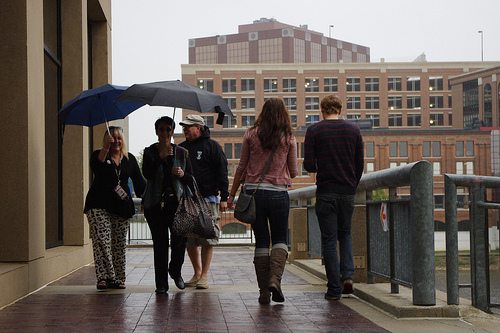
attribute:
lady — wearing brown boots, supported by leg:
[230, 97, 297, 307]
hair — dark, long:
[252, 101, 293, 151]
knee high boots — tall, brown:
[253, 244, 289, 304]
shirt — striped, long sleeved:
[304, 120, 363, 191]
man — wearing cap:
[180, 117, 226, 290]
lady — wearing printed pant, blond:
[88, 126, 146, 289]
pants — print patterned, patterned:
[88, 207, 126, 283]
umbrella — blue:
[59, 86, 147, 126]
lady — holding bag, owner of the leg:
[145, 117, 195, 295]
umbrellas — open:
[62, 83, 234, 126]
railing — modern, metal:
[358, 165, 499, 303]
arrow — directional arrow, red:
[379, 209, 387, 224]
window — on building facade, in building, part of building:
[387, 80, 405, 93]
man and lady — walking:
[145, 117, 212, 292]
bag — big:
[175, 178, 220, 240]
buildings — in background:
[183, 19, 499, 235]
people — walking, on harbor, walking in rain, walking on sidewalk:
[57, 80, 364, 303]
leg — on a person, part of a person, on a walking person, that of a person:
[147, 207, 169, 293]